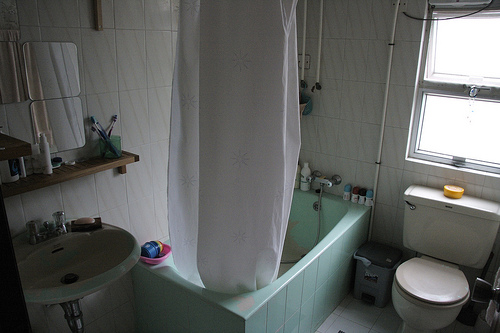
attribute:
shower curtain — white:
[163, 5, 307, 297]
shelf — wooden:
[1, 144, 141, 199]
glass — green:
[98, 135, 126, 161]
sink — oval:
[5, 217, 145, 309]